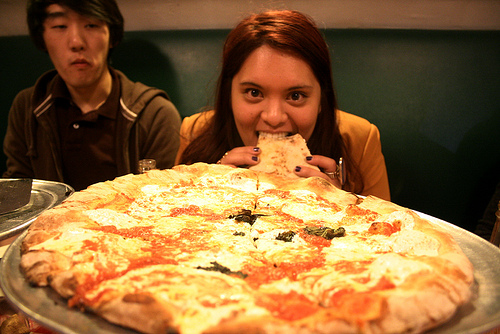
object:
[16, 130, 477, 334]
pizza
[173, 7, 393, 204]
girl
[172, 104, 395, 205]
shirt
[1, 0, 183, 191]
boy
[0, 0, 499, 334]
booth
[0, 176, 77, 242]
tray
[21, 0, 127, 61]
hair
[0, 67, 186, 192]
shirt